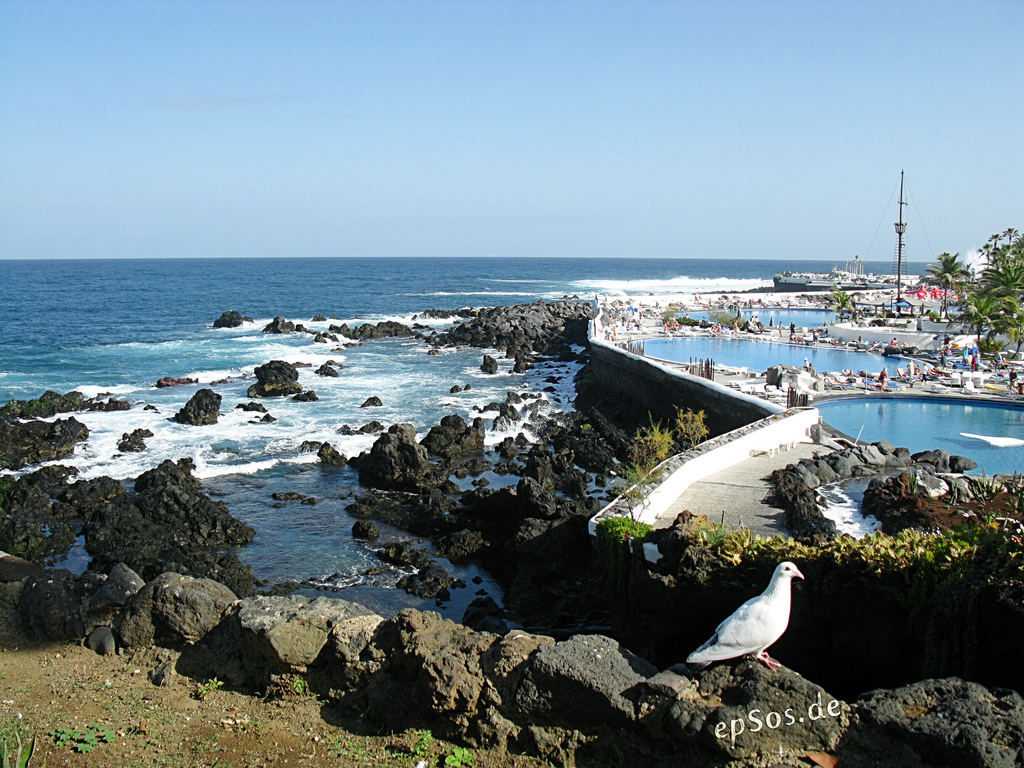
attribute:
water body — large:
[14, 258, 835, 615]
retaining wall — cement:
[556, 323, 812, 533]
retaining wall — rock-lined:
[14, 554, 1019, 758]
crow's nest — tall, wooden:
[884, 160, 917, 307]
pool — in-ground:
[831, 390, 1019, 475]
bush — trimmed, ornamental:
[656, 517, 1022, 647]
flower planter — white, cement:
[597, 392, 820, 537]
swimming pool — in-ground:
[815, 385, 1016, 483]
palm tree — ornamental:
[925, 238, 978, 345]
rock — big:
[419, 406, 484, 471]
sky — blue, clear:
[1, 1, 1023, 263]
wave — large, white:
[565, 262, 782, 291]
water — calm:
[9, 258, 385, 302]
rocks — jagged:
[347, 396, 503, 498]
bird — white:
[673, 547, 808, 697]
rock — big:
[243, 355, 304, 401]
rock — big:
[214, 307, 254, 329]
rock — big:
[256, 314, 300, 338]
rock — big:
[361, 392, 387, 410]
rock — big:
[353, 422, 464, 498]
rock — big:
[210, 307, 252, 333]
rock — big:
[3, 417, 88, 472]